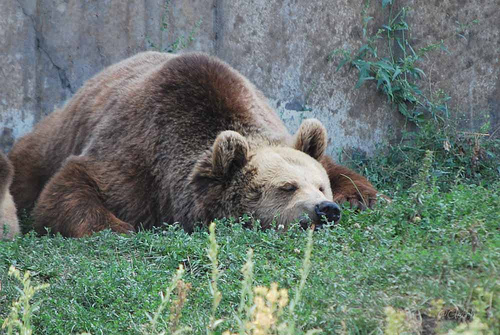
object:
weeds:
[335, 0, 447, 145]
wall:
[218, 2, 496, 139]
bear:
[0, 50, 394, 237]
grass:
[2, 235, 493, 335]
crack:
[18, 2, 74, 93]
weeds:
[207, 218, 225, 334]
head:
[211, 117, 337, 231]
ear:
[296, 117, 328, 162]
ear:
[212, 129, 248, 183]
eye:
[279, 183, 298, 193]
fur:
[1, 152, 14, 201]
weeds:
[340, 127, 429, 201]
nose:
[315, 201, 341, 225]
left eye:
[319, 186, 325, 192]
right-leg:
[31, 156, 136, 239]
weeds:
[1, 266, 51, 334]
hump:
[132, 52, 250, 84]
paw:
[334, 190, 392, 211]